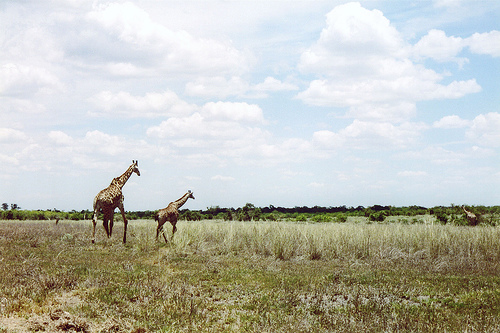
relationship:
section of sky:
[242, 100, 338, 149] [4, 4, 498, 207]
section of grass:
[332, 223, 412, 245] [0, 214, 500, 333]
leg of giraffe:
[107, 213, 127, 245] [88, 157, 147, 249]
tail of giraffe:
[90, 198, 98, 219] [88, 157, 147, 249]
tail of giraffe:
[152, 212, 159, 220] [152, 190, 195, 245]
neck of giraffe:
[163, 187, 193, 211] [136, 191, 226, 263]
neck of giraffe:
[114, 168, 136, 187] [91, 158, 141, 233]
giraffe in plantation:
[91, 157, 143, 247] [0, 192, 482, 292]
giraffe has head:
[91, 157, 143, 247] [129, 158, 142, 178]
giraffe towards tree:
[88, 157, 147, 249] [335, 213, 350, 222]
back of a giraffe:
[42, 126, 294, 327] [88, 157, 147, 249]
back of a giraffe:
[42, 126, 294, 327] [146, 187, 194, 240]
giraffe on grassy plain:
[152, 190, 195, 245] [1, 217, 498, 329]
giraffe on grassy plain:
[88, 157, 147, 249] [1, 217, 498, 329]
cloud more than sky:
[294, 0, 498, 127] [263, 37, 428, 142]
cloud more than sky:
[2, 0, 297, 117] [263, 37, 428, 142]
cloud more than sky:
[3, 98, 498, 204] [263, 37, 428, 142]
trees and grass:
[183, 202, 498, 219] [263, 212, 360, 220]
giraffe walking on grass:
[88, 157, 147, 249] [82, 232, 327, 283]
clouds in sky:
[5, 7, 495, 197] [4, 4, 498, 207]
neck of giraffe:
[114, 168, 136, 187] [88, 157, 147, 249]